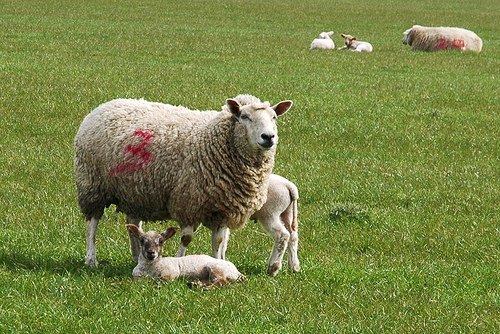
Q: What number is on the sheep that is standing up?
A: 3.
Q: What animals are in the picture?
A: Sheep.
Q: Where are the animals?
A: In a field.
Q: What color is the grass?
A: Green.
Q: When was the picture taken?
A: In the daytime.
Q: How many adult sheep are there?
A: 2.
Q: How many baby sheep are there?
A: 4.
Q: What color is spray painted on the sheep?
A: Red.